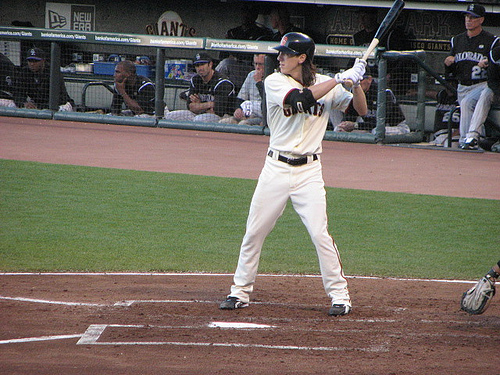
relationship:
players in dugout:
[140, 38, 499, 122] [70, 5, 468, 74]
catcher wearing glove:
[484, 239, 500, 295] [457, 269, 500, 315]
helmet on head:
[270, 31, 329, 62] [276, 51, 316, 77]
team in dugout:
[99, 47, 304, 130] [70, 5, 468, 74]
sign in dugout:
[37, 5, 125, 35] [70, 5, 468, 74]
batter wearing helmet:
[262, 28, 399, 175] [270, 31, 329, 62]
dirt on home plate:
[241, 311, 270, 323] [207, 307, 273, 339]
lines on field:
[58, 283, 412, 340] [1, 145, 492, 369]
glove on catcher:
[457, 269, 500, 325] [484, 239, 500, 295]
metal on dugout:
[75, 24, 268, 57] [70, 5, 468, 74]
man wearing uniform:
[257, 44, 346, 298] [268, 98, 327, 254]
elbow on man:
[285, 101, 321, 115] [257, 44, 346, 298]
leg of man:
[242, 207, 277, 302] [257, 44, 346, 298]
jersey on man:
[257, 87, 333, 147] [257, 44, 346, 298]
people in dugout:
[8, 36, 267, 108] [70, 5, 468, 74]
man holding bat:
[257, 44, 346, 298] [372, 4, 403, 71]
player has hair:
[266, 9, 368, 253] [303, 63, 319, 92]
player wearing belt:
[266, 9, 368, 253] [266, 149, 329, 163]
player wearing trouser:
[266, 9, 368, 253] [226, 152, 353, 297]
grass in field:
[18, 174, 469, 268] [1, 145, 492, 369]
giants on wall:
[135, 15, 225, 51] [92, 4, 307, 41]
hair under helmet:
[303, 63, 319, 92] [270, 31, 329, 62]